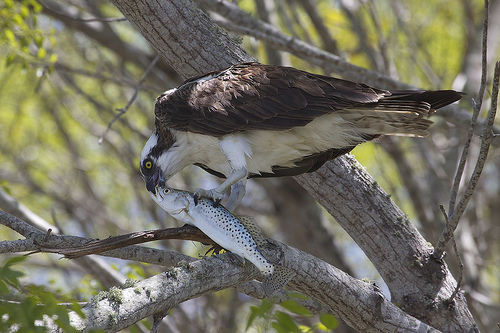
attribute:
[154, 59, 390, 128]
wing — brown 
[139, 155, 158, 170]
eye — yellow , black and yellow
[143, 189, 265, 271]
fish — yellow 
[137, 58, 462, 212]
bird — black 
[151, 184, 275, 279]
fish — black and yellow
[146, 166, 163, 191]
beak — black and white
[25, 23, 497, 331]
tree — Green 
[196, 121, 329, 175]
underbelly — white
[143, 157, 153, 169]
eye — Golden 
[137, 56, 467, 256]
bird — black and white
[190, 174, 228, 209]
bird talons — white 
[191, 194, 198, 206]
claw — black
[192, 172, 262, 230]
talon — bird's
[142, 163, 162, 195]
beak — black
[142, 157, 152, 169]
eye — yellow